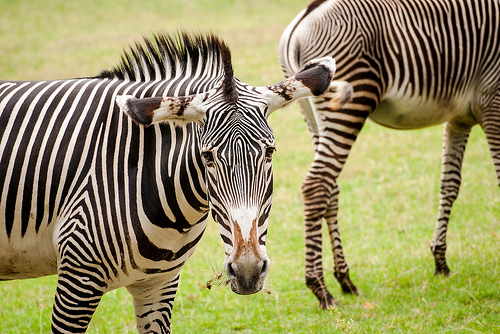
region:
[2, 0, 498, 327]
two zebras in a field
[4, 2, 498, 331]
a green grass field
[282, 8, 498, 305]
the backside of a zebra on the right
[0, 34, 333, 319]
front view of zebra on the left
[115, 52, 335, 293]
head of the left zebra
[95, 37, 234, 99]
the left zebra's black and white mane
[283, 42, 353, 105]
the right zebra's tail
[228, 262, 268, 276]
the left zebra's nostrils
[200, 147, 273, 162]
the left zebra's eyes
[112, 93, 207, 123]
the left zebra's right ear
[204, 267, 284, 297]
Food in a zebra's mouth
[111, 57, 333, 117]
A zebra's large ears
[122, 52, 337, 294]
The face of the zebra looking at the camera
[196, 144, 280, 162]
The zebra's eyes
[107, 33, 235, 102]
The black and white mane of a zebra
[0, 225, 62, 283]
The white belly of the zebra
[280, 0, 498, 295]
The back half of a zebra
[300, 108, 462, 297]
A zebra's legs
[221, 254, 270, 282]
A zebra's nose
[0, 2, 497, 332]
Grass behind the zebras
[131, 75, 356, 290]
Zebra looking straight ahead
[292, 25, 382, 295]
hind legs of a zebra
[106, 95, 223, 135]
ears poking out on a zebra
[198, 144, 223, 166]
Zebra with brown eyes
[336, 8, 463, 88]
black and white strips on a zebra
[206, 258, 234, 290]
Grass in the mouth of a zebra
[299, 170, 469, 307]
Zebra standing in the grass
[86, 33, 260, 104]
Hair spiked on a zebra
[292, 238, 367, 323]
Zebra walking in the grass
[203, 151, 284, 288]
Zebra with a long face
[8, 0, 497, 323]
There are two zebras.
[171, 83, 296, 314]
A zebra looking at the camera.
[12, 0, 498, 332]
The zebras are black and white.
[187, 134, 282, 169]
The eyes are brown.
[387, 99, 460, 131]
The stomach is mostly white.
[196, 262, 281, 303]
Food in the mouth.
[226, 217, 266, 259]
Brown on the nose.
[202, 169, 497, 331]
The grass is green.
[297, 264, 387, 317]
Weeds in the grass.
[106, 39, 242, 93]
Top of the mane is black.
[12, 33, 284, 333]
zebra staring at camera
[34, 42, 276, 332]
zebra chewing on grass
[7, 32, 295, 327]
zebra grazing for food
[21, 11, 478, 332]
two zebra grazing together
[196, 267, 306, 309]
grass in zebras mouth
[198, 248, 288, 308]
grass being chewed by zebra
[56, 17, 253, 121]
zebras hair is sticking up in mohawk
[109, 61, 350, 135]
zebras ears laying half way down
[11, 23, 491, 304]
two zebra standing in a field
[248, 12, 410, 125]
zebra with its tail on its back